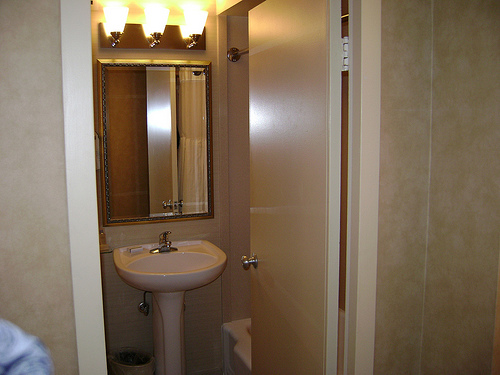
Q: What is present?
A: A sink.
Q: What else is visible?
A: A mirror.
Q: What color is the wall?
A: Brown.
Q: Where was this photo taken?
A: The bathroom.